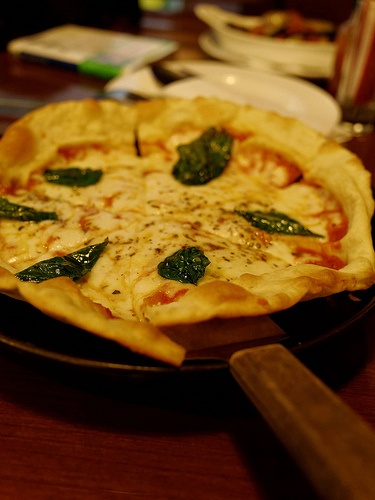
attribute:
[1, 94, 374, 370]
crust — thin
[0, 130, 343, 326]
cheese — melted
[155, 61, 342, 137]
plate — white, circular, empty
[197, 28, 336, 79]
plate — white, circular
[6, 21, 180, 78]
book — white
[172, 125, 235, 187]
spinach — large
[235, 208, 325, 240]
basil leaf — cooked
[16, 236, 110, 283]
basil leaf — cooked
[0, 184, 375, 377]
pizza dish — black, metal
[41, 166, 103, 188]
leaf spice — green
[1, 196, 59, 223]
leaf spice — green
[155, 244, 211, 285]
leaf spice — green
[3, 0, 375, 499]
table — brown, wood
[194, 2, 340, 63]
boat dish — white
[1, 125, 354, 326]
herbs — dry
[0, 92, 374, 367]
pizza — fresh, small, cooked, sliced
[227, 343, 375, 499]
handle — wooden